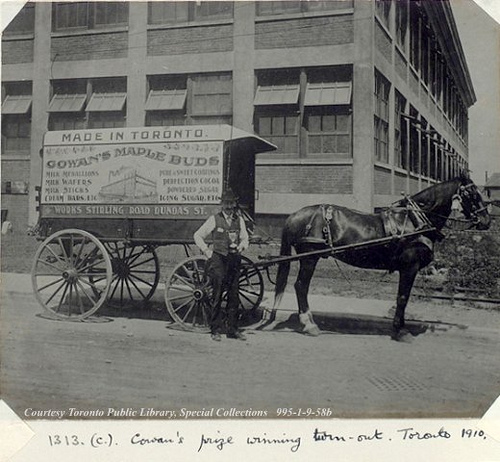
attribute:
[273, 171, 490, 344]
horse — black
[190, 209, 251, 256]
shirt — white, long sleeved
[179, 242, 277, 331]
pants — black